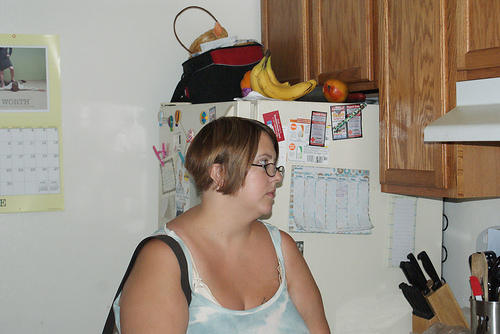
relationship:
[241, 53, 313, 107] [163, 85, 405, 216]
bananas on fridge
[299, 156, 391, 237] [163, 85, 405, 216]
calendar on fridge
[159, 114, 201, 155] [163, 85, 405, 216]
magnets on fridge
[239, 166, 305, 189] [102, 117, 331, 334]
glasses on lady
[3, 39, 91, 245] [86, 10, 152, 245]
calendar on wall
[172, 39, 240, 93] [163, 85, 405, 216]
bag on fridge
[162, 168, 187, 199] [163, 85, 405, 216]
papers on fridge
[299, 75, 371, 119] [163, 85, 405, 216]
apple on fridge